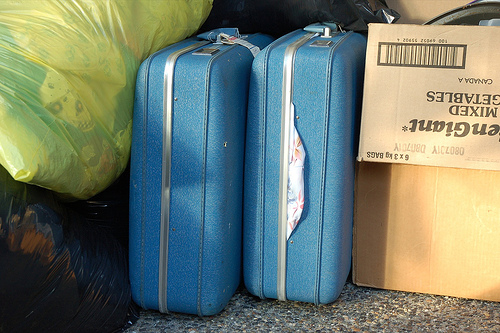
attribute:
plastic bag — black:
[4, 197, 134, 324]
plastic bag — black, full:
[0, 172, 142, 327]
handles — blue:
[191, 26, 361, 62]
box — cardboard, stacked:
[346, 9, 498, 164]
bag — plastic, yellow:
[4, 4, 107, 193]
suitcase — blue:
[209, 32, 374, 324]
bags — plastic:
[1, 0, 216, 202]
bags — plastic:
[1, 161, 139, 331]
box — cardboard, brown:
[352, 19, 499, 304]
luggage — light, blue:
[246, 15, 372, 322]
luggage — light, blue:
[124, 25, 280, 322]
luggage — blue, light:
[238, 20, 367, 304]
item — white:
[287, 102, 308, 237]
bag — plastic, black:
[0, 164, 130, 332]